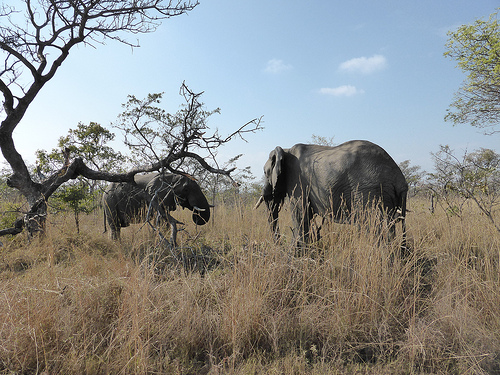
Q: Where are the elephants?
A: In a field.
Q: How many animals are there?
A: Two.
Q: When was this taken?
A: Daytime.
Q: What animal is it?
A: Elephant.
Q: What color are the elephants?
A: Gray.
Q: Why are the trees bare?
A: Animals ate the leaves.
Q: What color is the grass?
A: Brown.